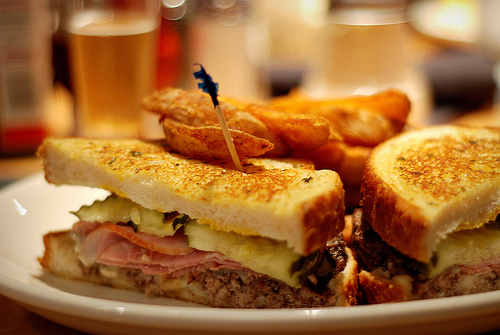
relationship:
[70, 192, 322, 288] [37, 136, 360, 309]
pickles on sandwich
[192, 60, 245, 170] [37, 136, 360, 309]
toothpick in sandwich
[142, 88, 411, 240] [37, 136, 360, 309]
french fries behind sandwich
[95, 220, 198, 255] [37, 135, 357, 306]
meat between bread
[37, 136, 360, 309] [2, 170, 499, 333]
sandwich on plate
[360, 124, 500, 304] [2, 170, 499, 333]
sandwich on plate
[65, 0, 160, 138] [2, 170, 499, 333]
glass behind plate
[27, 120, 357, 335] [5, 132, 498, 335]
sandwich on plate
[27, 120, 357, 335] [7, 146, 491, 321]
sandwich on plate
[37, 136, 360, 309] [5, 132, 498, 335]
sandwich on plate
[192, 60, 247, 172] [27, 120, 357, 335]
toothpick in sandwich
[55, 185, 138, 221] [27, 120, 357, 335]
pickle on sandwich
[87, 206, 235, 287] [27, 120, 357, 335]
meat on sandwich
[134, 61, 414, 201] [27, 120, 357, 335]
fries touching sandwich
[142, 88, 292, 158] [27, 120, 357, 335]
french fries behind sandwich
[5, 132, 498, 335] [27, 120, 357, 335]
plate with sandwich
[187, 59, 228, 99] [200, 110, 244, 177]
plastic on toothpick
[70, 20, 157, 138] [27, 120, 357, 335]
beer behind sandwich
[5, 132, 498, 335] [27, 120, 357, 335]
plate under sandwich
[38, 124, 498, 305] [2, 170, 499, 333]
sandwich on plate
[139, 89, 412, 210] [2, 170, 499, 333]
fries on plate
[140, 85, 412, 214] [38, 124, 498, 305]
french fries by sandwich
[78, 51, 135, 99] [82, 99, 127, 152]
beer in glass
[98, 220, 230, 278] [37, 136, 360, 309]
meat in sandwich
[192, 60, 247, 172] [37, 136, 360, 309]
toothpick on top of sandwich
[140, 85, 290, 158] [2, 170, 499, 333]
french fry on plate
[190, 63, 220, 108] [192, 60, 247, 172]
plastic on toothpick